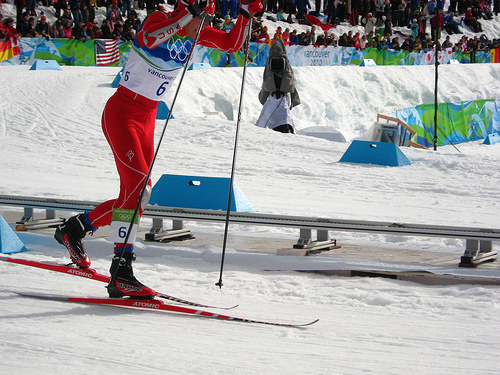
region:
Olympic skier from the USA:
[60, 1, 262, 315]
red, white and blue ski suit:
[83, 6, 258, 243]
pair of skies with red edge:
[0, 244, 325, 336]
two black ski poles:
[118, 21, 254, 287]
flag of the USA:
[89, 36, 131, 67]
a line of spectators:
[251, 11, 498, 51]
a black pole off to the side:
[408, 5, 450, 153]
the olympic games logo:
[162, 36, 194, 62]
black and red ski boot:
[97, 239, 159, 305]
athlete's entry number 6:
[116, 54, 171, 258]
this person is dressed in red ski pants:
[66, 101, 286, 371]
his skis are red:
[18, 238, 318, 355]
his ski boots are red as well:
[25, 203, 178, 340]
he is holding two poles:
[49, 1, 300, 364]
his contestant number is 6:
[105, 210, 141, 253]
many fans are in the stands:
[23, 7, 467, 47]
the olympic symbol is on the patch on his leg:
[113, 204, 135, 226]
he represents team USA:
[28, 6, 237, 347]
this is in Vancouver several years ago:
[296, 44, 353, 81]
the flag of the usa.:
[85, 32, 127, 69]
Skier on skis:
[82, 12, 282, 311]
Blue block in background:
[338, 128, 415, 169]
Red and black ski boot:
[91, 240, 177, 310]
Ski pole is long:
[108, 24, 208, 282]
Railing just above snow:
[15, 184, 497, 246]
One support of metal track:
[276, 232, 366, 245]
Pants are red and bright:
[77, 77, 178, 247]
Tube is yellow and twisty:
[382, 102, 442, 155]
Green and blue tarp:
[398, 89, 499, 146]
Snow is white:
[211, 107, 492, 244]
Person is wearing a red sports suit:
[61, 2, 278, 300]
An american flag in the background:
[87, 30, 127, 73]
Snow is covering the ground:
[5, 70, 499, 365]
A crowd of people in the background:
[5, 4, 495, 51]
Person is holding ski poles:
[95, 2, 267, 294]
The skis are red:
[3, 251, 332, 331]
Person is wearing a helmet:
[171, 3, 245, 38]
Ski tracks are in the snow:
[12, 80, 102, 169]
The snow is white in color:
[7, 72, 499, 356]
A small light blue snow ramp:
[324, 132, 420, 174]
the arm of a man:
[198, 10, 255, 60]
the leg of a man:
[97, 102, 154, 252]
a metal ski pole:
[211, 6, 267, 296]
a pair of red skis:
[0, 250, 324, 332]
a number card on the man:
[151, 76, 171, 101]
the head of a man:
[173, 0, 220, 46]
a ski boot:
[48, 205, 103, 276]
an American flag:
[88, 35, 125, 72]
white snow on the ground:
[3, 60, 498, 373]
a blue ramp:
[331, 132, 415, 175]